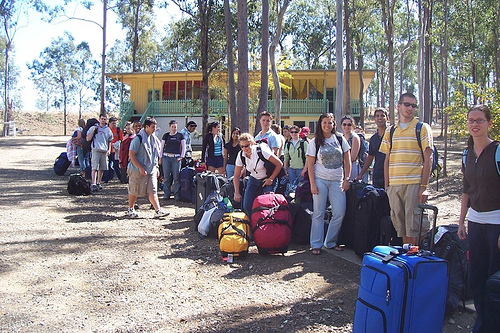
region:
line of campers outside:
[52, 49, 467, 306]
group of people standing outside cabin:
[57, 70, 444, 252]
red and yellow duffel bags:
[213, 186, 315, 269]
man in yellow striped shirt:
[378, 78, 438, 242]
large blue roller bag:
[347, 235, 437, 331]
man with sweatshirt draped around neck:
[130, 112, 176, 221]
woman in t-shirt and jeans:
[305, 103, 354, 250]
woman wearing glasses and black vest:
[450, 93, 497, 195]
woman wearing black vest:
[448, 90, 498, 229]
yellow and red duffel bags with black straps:
[215, 195, 287, 263]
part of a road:
[213, 285, 229, 303]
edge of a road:
[121, 199, 146, 246]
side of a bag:
[392, 269, 399, 294]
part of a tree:
[470, 86, 493, 101]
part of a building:
[182, 68, 194, 77]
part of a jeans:
[322, 219, 329, 226]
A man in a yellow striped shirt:
[380, 90, 437, 243]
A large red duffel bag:
[251, 185, 293, 252]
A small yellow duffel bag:
[216, 208, 252, 256]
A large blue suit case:
[352, 240, 452, 332]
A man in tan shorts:
[123, 115, 170, 219]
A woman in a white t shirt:
[304, 108, 350, 259]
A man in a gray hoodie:
[81, 110, 116, 187]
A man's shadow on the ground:
[274, 248, 349, 291]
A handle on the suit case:
[410, 199, 441, 251]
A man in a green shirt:
[282, 123, 311, 188]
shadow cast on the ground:
[38, 238, 139, 251]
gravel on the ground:
[76, 261, 165, 278]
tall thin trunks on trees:
[188, 49, 286, 108]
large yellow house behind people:
[112, 61, 399, 94]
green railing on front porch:
[141, 91, 333, 116]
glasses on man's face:
[391, 95, 441, 120]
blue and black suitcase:
[352, 234, 452, 314]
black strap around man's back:
[127, 125, 159, 154]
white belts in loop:
[158, 148, 192, 160]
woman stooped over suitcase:
[213, 123, 287, 185]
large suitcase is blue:
[353, 244, 445, 329]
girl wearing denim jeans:
[459, 104, 497, 324]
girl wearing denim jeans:
[310, 114, 345, 256]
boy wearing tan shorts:
[380, 90, 427, 242]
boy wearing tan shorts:
[127, 119, 168, 218]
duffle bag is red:
[252, 191, 292, 252]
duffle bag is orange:
[220, 210, 250, 251]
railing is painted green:
[122, 101, 365, 115]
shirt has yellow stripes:
[380, 122, 434, 183]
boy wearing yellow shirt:
[377, 90, 437, 242]